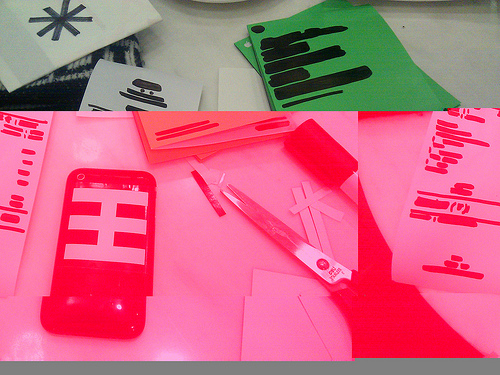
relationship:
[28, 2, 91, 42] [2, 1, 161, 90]
star on card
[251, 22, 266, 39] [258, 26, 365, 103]
dot and lines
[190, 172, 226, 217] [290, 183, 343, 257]
thin paper strips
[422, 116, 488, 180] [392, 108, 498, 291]
items on receipt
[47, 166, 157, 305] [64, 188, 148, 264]
cell with lines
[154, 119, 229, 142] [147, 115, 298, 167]
lines on bottom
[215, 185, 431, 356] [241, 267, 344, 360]
scissors on paper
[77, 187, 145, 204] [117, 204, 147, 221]
white over black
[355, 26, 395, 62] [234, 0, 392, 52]
green on top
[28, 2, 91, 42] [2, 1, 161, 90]
star on paper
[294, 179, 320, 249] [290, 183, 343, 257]
paper in strips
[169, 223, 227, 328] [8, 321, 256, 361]
pink on table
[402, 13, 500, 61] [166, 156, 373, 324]
table with things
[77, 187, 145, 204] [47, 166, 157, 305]
tape on iphone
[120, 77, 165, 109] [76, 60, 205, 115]
black on paper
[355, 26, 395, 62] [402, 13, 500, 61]
green on table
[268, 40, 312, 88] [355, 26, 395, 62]
black on green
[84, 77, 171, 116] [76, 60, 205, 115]
marker on paper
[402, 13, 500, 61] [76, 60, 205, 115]
table with paper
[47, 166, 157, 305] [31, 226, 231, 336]
cell in red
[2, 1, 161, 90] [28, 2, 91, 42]
paper with star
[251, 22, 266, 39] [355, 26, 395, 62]
dot on green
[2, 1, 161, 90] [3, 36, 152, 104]
paper on hat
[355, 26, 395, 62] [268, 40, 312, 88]
green with black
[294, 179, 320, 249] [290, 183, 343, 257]
white paper strips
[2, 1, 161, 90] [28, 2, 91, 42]
paper has star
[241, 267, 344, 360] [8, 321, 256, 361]
paper on table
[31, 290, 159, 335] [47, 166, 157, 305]
case off phone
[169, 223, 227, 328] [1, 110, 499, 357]
pink highlighted picture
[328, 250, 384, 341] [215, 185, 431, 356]
bottom of scissors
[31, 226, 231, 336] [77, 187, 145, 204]
red marked white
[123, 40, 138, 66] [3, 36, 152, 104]
grey on hat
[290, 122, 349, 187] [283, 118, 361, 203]
something in a bottle